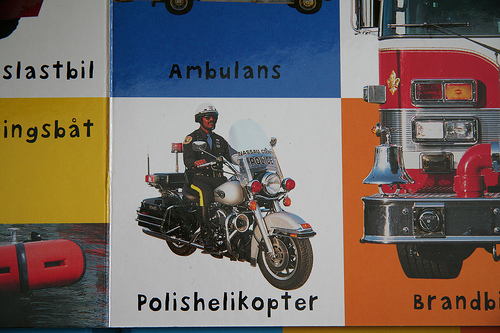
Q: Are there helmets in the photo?
A: Yes, there is a helmet.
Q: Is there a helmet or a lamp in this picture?
A: Yes, there is a helmet.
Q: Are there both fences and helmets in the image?
A: No, there is a helmet but no fences.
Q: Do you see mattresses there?
A: No, there are no mattresses.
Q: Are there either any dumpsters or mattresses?
A: No, there are no mattresses or dumpsters.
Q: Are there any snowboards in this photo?
A: No, there are no snowboards.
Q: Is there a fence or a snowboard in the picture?
A: No, there are no snowboards or fences.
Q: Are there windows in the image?
A: Yes, there is a window.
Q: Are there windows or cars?
A: Yes, there is a window.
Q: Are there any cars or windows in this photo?
A: Yes, there is a window.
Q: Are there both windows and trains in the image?
A: No, there is a window but no trains.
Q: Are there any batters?
A: No, there are no batters.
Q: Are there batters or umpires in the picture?
A: No, there are no batters or umpires.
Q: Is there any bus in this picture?
A: No, there are no buses.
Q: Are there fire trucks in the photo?
A: Yes, there is a fire truck.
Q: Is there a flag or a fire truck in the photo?
A: Yes, there is a fire truck.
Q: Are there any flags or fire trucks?
A: Yes, there is a fire truck.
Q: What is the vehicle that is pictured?
A: The vehicle is a fire truck.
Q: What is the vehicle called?
A: The vehicle is a fire truck.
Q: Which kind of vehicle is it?
A: The vehicle is a fire truck.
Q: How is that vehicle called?
A: This is a fire truck.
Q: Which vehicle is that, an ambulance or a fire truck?
A: This is a fire truck.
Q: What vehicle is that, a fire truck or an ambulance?
A: This is a fire truck.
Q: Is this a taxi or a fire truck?
A: This is a fire truck.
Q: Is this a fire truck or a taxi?
A: This is a fire truck.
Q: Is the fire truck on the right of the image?
A: Yes, the fire truck is on the right of the image.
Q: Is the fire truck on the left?
A: No, the fire truck is on the right of the image.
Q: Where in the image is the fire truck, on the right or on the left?
A: The fire truck is on the right of the image.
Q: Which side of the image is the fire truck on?
A: The fire truck is on the right of the image.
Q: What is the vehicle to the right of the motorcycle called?
A: The vehicle is a fire truck.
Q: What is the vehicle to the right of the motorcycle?
A: The vehicle is a fire truck.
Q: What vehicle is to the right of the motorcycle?
A: The vehicle is a fire truck.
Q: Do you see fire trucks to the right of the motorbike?
A: Yes, there is a fire truck to the right of the motorbike.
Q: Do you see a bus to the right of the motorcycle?
A: No, there is a fire truck to the right of the motorcycle.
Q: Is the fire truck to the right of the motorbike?
A: Yes, the fire truck is to the right of the motorbike.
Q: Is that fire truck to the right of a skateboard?
A: No, the fire truck is to the right of the motorbike.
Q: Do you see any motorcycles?
A: Yes, there is a motorcycle.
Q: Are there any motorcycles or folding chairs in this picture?
A: Yes, there is a motorcycle.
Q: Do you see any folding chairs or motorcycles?
A: Yes, there is a motorcycle.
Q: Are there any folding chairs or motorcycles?
A: Yes, there is a motorcycle.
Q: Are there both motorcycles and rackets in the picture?
A: No, there is a motorcycle but no rackets.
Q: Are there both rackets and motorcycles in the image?
A: No, there is a motorcycle but no rackets.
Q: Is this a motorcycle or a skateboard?
A: This is a motorcycle.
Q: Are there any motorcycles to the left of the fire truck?
A: Yes, there is a motorcycle to the left of the fire truck.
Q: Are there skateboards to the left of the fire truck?
A: No, there is a motorcycle to the left of the fire truck.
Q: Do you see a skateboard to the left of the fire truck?
A: No, there is a motorcycle to the left of the fire truck.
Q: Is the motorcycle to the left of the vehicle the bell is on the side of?
A: Yes, the motorcycle is to the left of the fire truck.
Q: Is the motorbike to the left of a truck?
A: No, the motorbike is to the left of the fire truck.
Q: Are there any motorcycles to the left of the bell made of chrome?
A: Yes, there is a motorcycle to the left of the bell.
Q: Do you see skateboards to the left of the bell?
A: No, there is a motorcycle to the left of the bell.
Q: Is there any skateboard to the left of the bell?
A: No, there is a motorcycle to the left of the bell.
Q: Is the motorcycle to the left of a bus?
A: No, the motorcycle is to the left of the bell.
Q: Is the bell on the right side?
A: Yes, the bell is on the right of the image.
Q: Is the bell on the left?
A: No, the bell is on the right of the image.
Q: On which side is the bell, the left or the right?
A: The bell is on the right of the image.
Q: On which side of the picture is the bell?
A: The bell is on the right of the image.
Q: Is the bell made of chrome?
A: Yes, the bell is made of chrome.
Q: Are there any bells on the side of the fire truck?
A: Yes, there is a bell on the side of the fire truck.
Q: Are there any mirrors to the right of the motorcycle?
A: No, there is a bell to the right of the motorcycle.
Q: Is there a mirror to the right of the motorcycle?
A: No, there is a bell to the right of the motorcycle.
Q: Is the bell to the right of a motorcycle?
A: Yes, the bell is to the right of a motorcycle.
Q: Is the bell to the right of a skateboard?
A: No, the bell is to the right of a motorcycle.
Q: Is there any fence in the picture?
A: No, there are no fences.